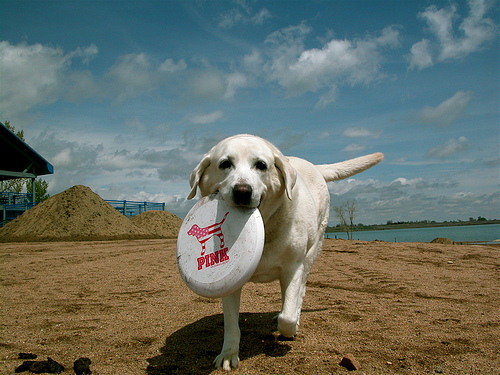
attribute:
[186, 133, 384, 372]
dog — white, walking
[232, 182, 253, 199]
nose — black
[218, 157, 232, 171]
eye — black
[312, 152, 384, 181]
tail — swishing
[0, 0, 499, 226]
sky — blue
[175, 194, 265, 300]
frisbee — white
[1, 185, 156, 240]
sand — piled, mounded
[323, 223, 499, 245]
water — blue, small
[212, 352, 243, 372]
paw — white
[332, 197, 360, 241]
tree — dead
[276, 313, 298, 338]
paw — raised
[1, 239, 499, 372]
sand — brown, messy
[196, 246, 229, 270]
word — pink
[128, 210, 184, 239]
dirt — piled